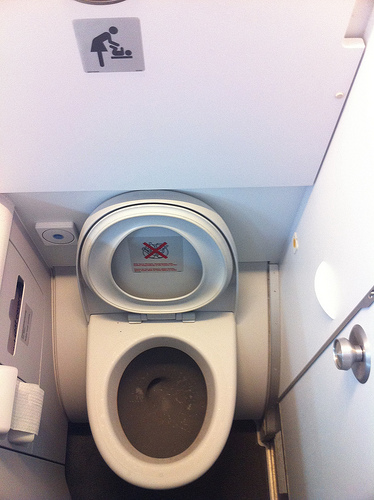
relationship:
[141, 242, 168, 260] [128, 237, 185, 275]
x on sign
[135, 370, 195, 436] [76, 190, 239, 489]
dirt in toilet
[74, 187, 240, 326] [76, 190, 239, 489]
lid of toilet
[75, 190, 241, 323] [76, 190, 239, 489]
lid on toilet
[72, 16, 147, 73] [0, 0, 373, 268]
symbol on wall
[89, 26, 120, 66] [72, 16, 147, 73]
woman on symbol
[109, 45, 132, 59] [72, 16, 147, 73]
baby on symbol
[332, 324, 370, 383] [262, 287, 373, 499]
knob on door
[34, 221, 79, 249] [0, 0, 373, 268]
sensor mounted on wall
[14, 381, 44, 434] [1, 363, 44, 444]
toilet paper on rack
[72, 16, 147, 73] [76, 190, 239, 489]
symbol above toilet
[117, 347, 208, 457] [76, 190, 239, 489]
bowl of toilet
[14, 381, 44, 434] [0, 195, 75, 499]
toilet paper on wall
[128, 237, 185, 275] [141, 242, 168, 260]
sign with x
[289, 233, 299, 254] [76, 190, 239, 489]
button near toilet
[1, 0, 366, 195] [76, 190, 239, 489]
changing table above toilet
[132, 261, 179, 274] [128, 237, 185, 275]
lettering on sign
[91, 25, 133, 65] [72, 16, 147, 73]
graphic on symbol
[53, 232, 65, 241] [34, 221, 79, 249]
button on sensor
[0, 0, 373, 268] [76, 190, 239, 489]
wall behind toilet